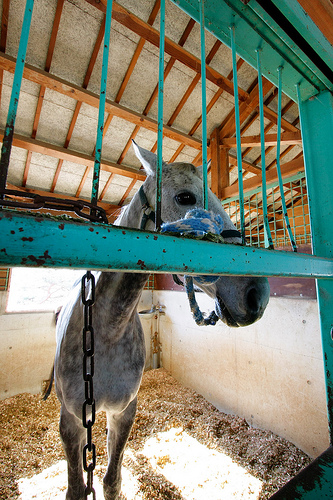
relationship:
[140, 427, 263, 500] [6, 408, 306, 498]
light on ground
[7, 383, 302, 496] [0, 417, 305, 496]
floor covered in sawdust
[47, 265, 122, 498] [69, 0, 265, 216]
chain on bars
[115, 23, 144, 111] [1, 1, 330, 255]
rafter on ceiling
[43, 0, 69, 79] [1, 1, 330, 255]
rafter on ceiling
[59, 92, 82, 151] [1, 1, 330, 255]
rafter on ceiling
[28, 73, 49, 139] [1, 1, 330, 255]
rafter on ceiling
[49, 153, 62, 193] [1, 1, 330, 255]
rafter on ceiling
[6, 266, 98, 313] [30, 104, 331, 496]
window shines into stall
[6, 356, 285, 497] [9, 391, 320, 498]
bedding covers floor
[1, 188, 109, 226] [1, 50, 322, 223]
chain wove in fence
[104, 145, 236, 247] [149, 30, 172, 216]
horse tied to bar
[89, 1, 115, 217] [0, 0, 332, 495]
bar painted aqua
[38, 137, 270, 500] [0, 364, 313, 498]
horse standing in chips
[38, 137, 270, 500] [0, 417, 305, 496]
horse standing in sawdust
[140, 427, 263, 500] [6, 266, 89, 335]
light pearing in window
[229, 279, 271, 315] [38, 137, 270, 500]
nose on horse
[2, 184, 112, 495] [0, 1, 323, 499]
chain in horse stall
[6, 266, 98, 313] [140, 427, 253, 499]
window lets in light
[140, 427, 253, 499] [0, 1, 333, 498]
light shines in horse stall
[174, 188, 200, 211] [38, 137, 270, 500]
eye of horse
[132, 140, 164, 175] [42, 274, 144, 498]
ear of horse